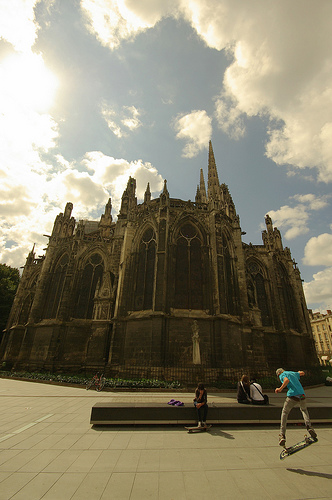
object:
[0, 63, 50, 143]
white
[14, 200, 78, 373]
tower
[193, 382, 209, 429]
skateboarder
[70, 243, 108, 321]
window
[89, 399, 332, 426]
bench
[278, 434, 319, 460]
skateboard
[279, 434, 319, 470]
trick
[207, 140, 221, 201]
spires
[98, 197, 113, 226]
steeples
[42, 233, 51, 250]
gargoyle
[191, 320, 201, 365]
statue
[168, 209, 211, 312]
church windows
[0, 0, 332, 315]
sky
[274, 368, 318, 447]
boy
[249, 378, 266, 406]
person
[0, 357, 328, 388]
gate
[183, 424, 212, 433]
skateboard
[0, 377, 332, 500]
pavement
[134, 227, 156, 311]
glass windows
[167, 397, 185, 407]
purple clothing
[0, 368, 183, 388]
greenery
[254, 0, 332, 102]
dark/cloud part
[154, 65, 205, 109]
blue/sky part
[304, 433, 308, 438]
skateboard wheels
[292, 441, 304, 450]
skateboard section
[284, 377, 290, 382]
elbow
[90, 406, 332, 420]
bench section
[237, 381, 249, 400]
back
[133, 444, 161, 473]
section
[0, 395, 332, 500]
skating park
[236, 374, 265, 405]
couple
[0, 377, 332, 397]
path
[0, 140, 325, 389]
cathedral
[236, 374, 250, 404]
girl